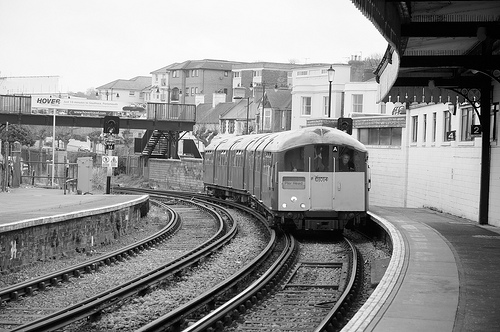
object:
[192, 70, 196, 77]
windows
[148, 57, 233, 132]
buildings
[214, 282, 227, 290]
rails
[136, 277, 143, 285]
rails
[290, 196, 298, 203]
lights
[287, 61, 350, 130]
houses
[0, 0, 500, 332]
station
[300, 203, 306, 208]
lights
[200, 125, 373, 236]
train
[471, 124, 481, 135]
number 2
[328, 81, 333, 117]
lamp post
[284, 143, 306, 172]
window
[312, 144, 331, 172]
window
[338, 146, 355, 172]
window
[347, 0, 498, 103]
shelter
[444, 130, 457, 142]
sign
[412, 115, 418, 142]
window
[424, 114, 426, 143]
window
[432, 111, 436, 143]
window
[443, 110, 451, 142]
window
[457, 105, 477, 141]
window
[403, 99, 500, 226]
building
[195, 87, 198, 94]
windows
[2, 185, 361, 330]
track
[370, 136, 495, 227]
wall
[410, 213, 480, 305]
train platform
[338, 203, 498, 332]
platform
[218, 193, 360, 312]
gravel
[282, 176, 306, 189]
sign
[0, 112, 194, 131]
bridge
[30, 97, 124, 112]
advertisement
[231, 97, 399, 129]
sign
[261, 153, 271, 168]
windows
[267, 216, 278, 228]
wheels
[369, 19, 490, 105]
awning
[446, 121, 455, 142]
4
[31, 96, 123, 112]
sign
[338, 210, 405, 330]
line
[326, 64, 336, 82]
lamp